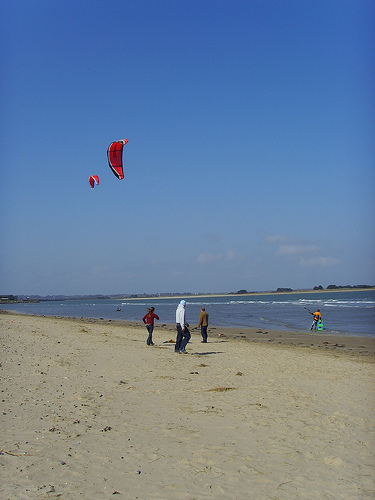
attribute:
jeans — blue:
[198, 326, 210, 341]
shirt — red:
[141, 311, 159, 323]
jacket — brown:
[195, 310, 211, 327]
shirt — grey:
[172, 305, 186, 329]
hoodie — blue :
[179, 298, 185, 306]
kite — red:
[81, 174, 98, 191]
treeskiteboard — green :
[314, 318, 325, 333]